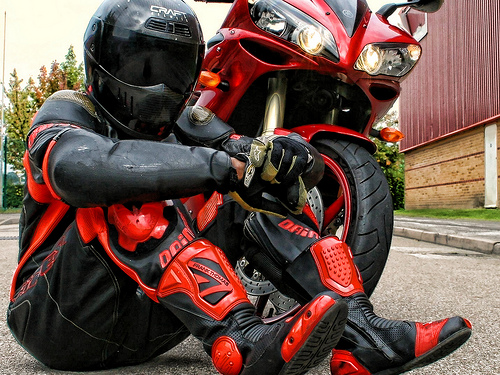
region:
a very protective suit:
[2, 0, 474, 373]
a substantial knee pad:
[97, 188, 177, 259]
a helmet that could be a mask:
[75, 0, 213, 145]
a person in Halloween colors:
[5, 5, 470, 374]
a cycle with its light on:
[202, 0, 443, 295]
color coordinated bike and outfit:
[7, 3, 469, 365]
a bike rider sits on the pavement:
[0, 1, 470, 371]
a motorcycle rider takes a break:
[6, 0, 473, 374]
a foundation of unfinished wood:
[396, 110, 497, 212]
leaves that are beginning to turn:
[0, 25, 95, 208]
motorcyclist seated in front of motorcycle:
[15, 15, 485, 365]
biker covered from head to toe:
[6, 8, 480, 364]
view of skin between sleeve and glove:
[216, 140, 249, 185]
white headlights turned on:
[245, 15, 425, 90]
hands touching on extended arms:
[25, 95, 327, 235]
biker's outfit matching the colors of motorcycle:
[36, 25, 467, 356]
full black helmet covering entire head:
[60, 1, 226, 131]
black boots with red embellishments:
[141, 230, 476, 365]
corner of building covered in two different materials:
[381, 10, 491, 225]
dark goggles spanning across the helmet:
[77, 13, 218, 95]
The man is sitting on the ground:
[48, 70, 404, 373]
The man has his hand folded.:
[221, 136, 337, 208]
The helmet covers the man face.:
[87, 9, 211, 141]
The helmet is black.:
[50, 16, 215, 125]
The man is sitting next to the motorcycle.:
[70, 15, 436, 286]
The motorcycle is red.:
[233, 0, 440, 137]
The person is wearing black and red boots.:
[161, 251, 477, 365]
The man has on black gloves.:
[257, 132, 333, 203]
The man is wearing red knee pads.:
[103, 195, 210, 270]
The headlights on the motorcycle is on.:
[287, 13, 427, 73]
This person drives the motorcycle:
[52, 21, 402, 329]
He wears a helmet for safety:
[55, 30, 278, 173]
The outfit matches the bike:
[49, 23, 480, 296]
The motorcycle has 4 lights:
[215, 20, 457, 158]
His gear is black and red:
[62, 89, 354, 347]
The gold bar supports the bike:
[251, 91, 430, 241]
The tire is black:
[281, 116, 423, 343]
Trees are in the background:
[4, 29, 216, 263]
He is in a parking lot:
[21, 69, 465, 341]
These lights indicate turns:
[185, 44, 436, 196]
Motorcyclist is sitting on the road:
[0, 0, 457, 368]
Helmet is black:
[80, 0, 210, 140]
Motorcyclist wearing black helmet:
[8, 1, 476, 373]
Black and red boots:
[145, 230, 475, 365]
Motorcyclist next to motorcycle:
[198, 0, 480, 295]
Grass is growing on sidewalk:
[392, 200, 497, 260]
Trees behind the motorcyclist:
[5, 50, 76, 203]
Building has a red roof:
[400, 0, 496, 217]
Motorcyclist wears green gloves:
[205, 126, 326, 232]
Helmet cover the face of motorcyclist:
[8, 0, 498, 374]